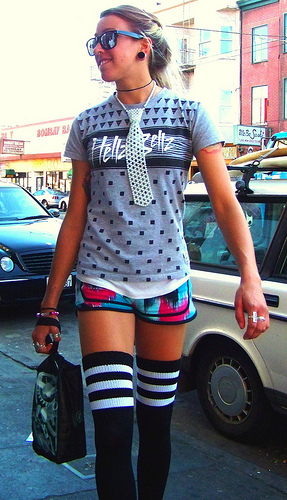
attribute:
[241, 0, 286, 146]
building — red, brick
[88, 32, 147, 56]
sunglasses — black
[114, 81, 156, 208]
tie — black, white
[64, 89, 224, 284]
shirt — grey, black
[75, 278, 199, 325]
shorts — pink, blue, black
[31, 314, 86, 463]
bag — white, black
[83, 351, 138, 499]
stocking — long, striped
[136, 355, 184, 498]
stocking — long, striped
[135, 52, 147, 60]
earring — black, guaged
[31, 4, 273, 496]
woman — smiling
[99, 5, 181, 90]
hair — color treated